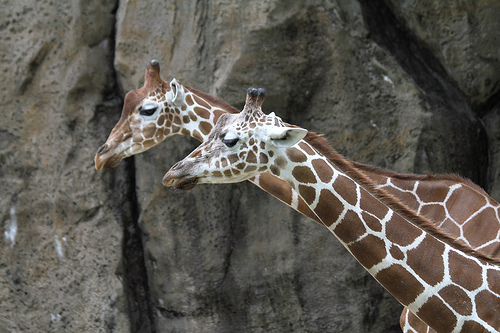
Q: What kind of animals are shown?
A: Giraffes.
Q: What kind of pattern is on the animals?
A: Spots.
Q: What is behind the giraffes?
A: A wall of stone.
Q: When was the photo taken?
A: In the afternoon.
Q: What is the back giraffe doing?
A: Sticking out it's tongue.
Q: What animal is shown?
A: Giraffe.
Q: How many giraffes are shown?
A: Two.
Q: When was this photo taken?
A: During the daytime.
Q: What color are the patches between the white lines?
A: Brown.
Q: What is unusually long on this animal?
A: Neck.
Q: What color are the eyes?
A: Black.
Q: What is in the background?
A: Rock wall.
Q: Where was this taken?
A: Zoo.